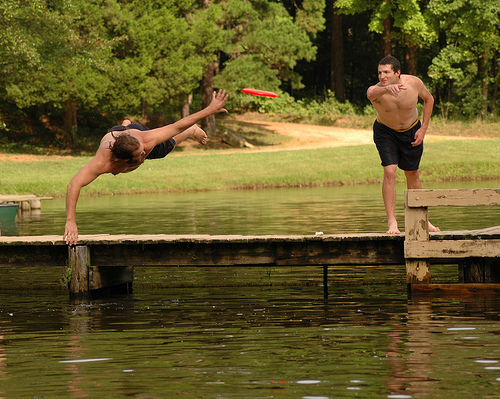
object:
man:
[364, 54, 441, 235]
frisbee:
[241, 88, 277, 98]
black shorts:
[108, 122, 177, 159]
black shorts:
[372, 117, 424, 172]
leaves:
[237, 1, 320, 70]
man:
[62, 88, 230, 247]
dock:
[0, 225, 500, 297]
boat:
[0, 202, 19, 223]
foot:
[385, 223, 401, 234]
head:
[110, 132, 147, 162]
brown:
[436, 195, 446, 199]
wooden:
[404, 240, 485, 259]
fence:
[404, 188, 500, 311]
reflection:
[388, 298, 436, 395]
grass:
[0, 139, 500, 198]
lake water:
[0, 180, 500, 399]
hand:
[411, 79, 435, 146]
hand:
[209, 88, 230, 113]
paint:
[403, 188, 499, 282]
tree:
[329, 0, 346, 104]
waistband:
[377, 118, 419, 133]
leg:
[382, 165, 400, 235]